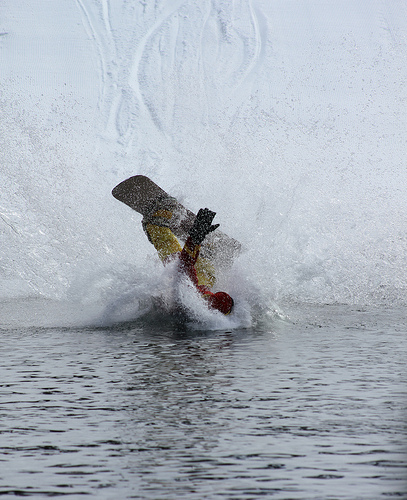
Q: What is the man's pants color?
A: Yellow.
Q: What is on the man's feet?
A: Board.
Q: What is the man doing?
A: Snowboarding.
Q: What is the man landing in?
A: Water.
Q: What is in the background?
A: A slope.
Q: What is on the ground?
A: Snow.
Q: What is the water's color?
A: Gray.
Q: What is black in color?
A: Snowboard.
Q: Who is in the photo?
A: A person.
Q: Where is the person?
A: In the water.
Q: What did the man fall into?
A: Water.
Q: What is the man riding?
A: Wakeboard.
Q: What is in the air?
A: Water.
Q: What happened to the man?
A: Wrecked.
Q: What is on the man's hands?
A: Gloves.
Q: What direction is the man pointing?
A: Upside down.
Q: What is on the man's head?
A: Hat.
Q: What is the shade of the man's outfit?
A: Yellow.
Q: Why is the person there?
A: They were snowboarding.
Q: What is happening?
A: They are falling in the water.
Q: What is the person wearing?
A: A snowboard.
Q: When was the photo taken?
A: During the day.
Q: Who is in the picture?
A: A snowboarder.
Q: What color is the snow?
A: White.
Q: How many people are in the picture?
A: One.